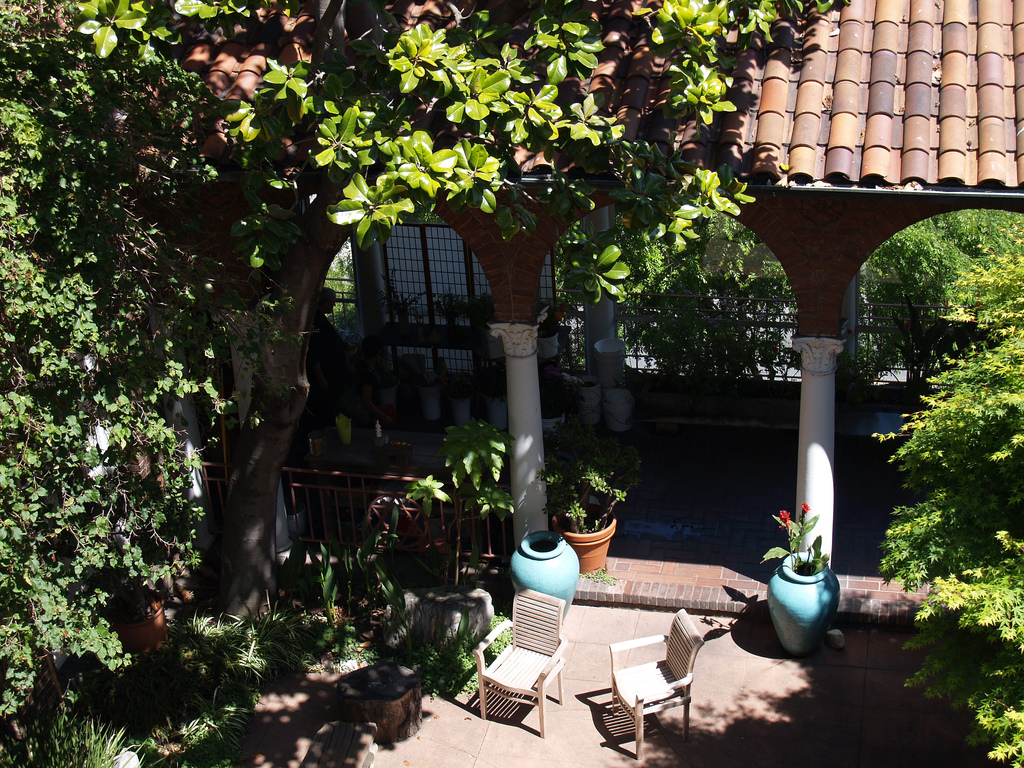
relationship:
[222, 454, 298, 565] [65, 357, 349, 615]
trunk of tree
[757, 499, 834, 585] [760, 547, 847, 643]
flowers in pot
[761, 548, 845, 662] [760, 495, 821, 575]
planter with flowers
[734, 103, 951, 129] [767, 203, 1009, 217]
surface of tile roof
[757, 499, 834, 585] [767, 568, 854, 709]
flowers in blue planter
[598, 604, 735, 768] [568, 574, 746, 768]
light on empty outdoor chair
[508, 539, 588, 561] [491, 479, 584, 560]
empty hole of blue planter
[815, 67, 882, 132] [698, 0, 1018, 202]
tile on top of roof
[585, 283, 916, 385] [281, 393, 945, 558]
fence at side of porch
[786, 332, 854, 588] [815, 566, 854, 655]
column at base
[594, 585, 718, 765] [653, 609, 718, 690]
chair has back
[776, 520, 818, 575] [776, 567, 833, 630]
flowers in planter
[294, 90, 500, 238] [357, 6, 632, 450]
leaves on tree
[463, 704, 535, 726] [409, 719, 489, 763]
shadow on ground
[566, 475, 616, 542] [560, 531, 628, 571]
shrub in planter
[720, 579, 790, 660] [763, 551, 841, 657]
shadow of a vase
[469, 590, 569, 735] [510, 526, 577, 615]
chair in front of a pot